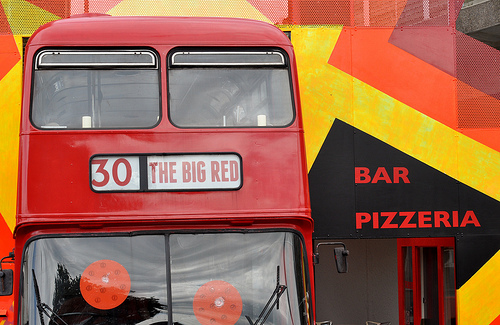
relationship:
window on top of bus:
[24, 39, 164, 145] [11, 3, 339, 321]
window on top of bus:
[161, 43, 301, 157] [11, 3, 339, 321]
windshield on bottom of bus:
[9, 218, 309, 322] [11, 3, 339, 321]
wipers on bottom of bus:
[26, 255, 291, 323] [11, 3, 339, 321]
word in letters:
[347, 156, 427, 193] [349, 154, 423, 192]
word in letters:
[347, 197, 479, 247] [355, 199, 484, 231]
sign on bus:
[89, 149, 247, 193] [11, 3, 339, 321]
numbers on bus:
[87, 145, 136, 205] [11, 3, 339, 321]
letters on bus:
[144, 152, 255, 192] [11, 3, 339, 321]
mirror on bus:
[309, 234, 354, 287] [11, 3, 339, 321]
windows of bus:
[15, 11, 321, 319] [11, 3, 339, 321]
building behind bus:
[275, 4, 484, 314] [11, 3, 339, 321]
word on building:
[354, 166, 413, 186] [303, 14, 483, 284]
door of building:
[387, 219, 467, 322] [293, 11, 483, 312]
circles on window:
[74, 256, 240, 323] [11, 218, 336, 322]